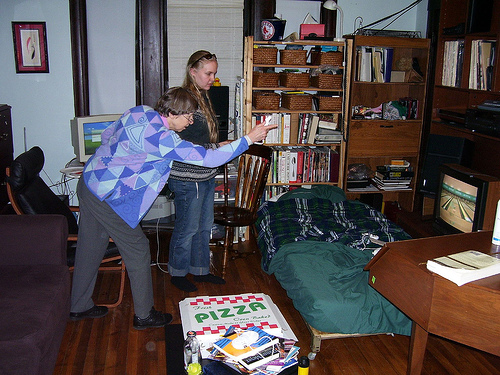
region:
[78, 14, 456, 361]
two women in a room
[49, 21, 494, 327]
two woman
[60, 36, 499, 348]
two women play a video game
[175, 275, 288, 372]
a pizza box on a table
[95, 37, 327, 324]
the woman is holding a game controller in her right hand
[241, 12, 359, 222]
a shelf with nine wicker baskets on it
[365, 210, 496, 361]
a wooden table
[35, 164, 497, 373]
the floor is wood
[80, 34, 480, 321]
the two women are playing a bowling game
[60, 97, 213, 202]
a computer is on the table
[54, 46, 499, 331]
Two people playing Wii bowling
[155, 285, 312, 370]
A pizza box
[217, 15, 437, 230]
A bookcase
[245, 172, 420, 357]
a roll-away cot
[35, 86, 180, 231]
A desk top computer in the background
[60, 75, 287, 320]
The older lady has on a multi-colored sweater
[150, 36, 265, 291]
The younger lady has really long hair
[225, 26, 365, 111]
Storage baskets on shelves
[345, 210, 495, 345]
A book on a table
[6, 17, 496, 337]
Two people playing in a very small, messy room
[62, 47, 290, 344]
Two persons in a bedroom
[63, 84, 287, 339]
Old woman has right hand extended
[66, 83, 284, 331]
Old woman wears glasses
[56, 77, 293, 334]
Old woman wears grey pants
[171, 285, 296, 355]
Box of pizza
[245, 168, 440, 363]
Bed has green cover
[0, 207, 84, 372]
Couch is purple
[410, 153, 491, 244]
Television on a shelve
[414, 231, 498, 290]
Book on a table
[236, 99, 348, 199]
Books in a shelve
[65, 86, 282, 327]
Lady in purple sweater playing game ontelevision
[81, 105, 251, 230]
Purple sweater on a lady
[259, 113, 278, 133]
White game controller in lady's hand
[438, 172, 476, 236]
Television screen displaying video game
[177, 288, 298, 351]
Red, white, and green pizza box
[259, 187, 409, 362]
Pull out bed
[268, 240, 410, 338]
Green cover on a pull out bed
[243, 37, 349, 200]
Full wooden bookcase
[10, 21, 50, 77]
Brown framed picture on blue wall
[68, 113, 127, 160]
Gray framed computer monitor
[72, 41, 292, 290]
Two women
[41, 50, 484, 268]
Two women playing a video game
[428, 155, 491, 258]
A turned on television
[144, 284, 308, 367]
A cardboard pizza box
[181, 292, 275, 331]
The word pizza in green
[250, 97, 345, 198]
books on a bookshelf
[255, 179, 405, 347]
A twin sized bed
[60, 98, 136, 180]
A computer monitor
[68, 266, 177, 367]
feet on a wood floor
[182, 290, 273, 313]
Red squares